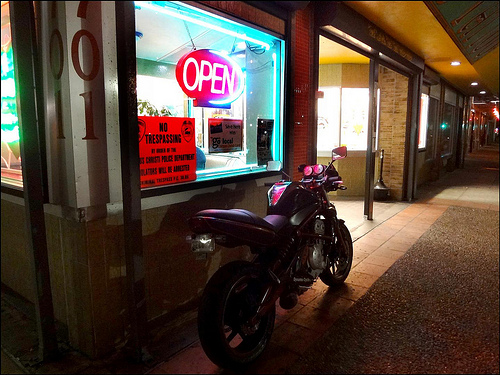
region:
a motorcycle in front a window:
[114, 26, 364, 373]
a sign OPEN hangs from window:
[138, 3, 285, 183]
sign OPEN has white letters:
[174, 45, 243, 102]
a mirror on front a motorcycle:
[321, 139, 355, 165]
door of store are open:
[313, 25, 399, 222]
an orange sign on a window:
[140, 105, 200, 184]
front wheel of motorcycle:
[311, 216, 357, 288]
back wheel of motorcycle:
[190, 260, 281, 370]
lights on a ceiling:
[441, 51, 497, 98]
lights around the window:
[131, 0, 285, 175]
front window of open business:
[130, 5, 294, 180]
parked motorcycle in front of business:
[170, 142, 360, 374]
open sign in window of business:
[172, 44, 244, 105]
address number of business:
[39, 0, 106, 155]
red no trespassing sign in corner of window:
[135, 109, 206, 190]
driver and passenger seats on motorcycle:
[177, 203, 295, 252]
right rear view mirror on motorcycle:
[327, 141, 357, 166]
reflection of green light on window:
[437, 110, 454, 138]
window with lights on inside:
[312, 78, 389, 159]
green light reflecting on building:
[438, 115, 453, 134]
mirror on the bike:
[332, 142, 348, 162]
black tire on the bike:
[198, 303, 224, 334]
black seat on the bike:
[236, 212, 265, 217]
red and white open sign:
[186, 57, 232, 103]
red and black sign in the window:
[136, 120, 192, 190]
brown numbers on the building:
[66, 2, 104, 159]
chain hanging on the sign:
[185, 20, 195, 40]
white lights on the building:
[451, 57, 463, 69]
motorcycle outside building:
[157, 142, 352, 372]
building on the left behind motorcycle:
[10, 0, 495, 352]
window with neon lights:
[125, 15, 285, 190]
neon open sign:
[171, 36, 243, 107]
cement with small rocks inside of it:
[286, 195, 497, 371]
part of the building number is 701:
[30, 0, 117, 206]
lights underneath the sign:
[446, 53, 496, 103]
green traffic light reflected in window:
[441, 118, 448, 128]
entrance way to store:
[322, 28, 422, 248]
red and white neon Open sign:
[175, 49, 241, 101]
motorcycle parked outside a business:
[189, 160, 359, 360]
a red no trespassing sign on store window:
[136, 117, 198, 188]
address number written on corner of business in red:
[41, 1, 103, 141]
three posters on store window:
[131, 108, 280, 190]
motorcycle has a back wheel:
[194, 258, 282, 370]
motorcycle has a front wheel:
[316, 218, 354, 287]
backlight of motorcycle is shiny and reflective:
[188, 228, 216, 256]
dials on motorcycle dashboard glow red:
[302, 161, 326, 179]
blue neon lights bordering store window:
[134, 1, 286, 191]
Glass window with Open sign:
[136, 0, 284, 188]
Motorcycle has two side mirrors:
[185, 144, 354, 373]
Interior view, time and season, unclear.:
[0, 0, 495, 371]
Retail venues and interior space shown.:
[0, 17, 495, 369]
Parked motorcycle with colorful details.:
[195, 157, 365, 362]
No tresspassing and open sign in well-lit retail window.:
[141, 30, 287, 176]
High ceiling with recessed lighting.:
[395, 18, 497, 108]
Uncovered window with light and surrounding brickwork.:
[317, 71, 404, 152]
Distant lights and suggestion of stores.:
[449, 88, 499, 163]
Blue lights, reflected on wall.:
[440, 114, 485, 138]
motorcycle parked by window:
[179, 132, 369, 374]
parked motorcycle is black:
[174, 138, 371, 370]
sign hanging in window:
[135, 108, 201, 197]